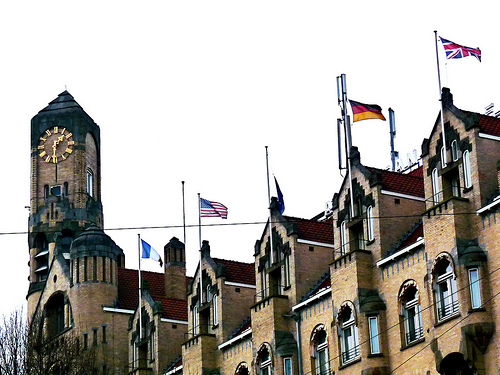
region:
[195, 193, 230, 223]
Flag of the United States of America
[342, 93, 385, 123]
Flag of Germany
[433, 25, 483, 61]
Flag of Great Britain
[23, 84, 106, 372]
Clock tower with green roof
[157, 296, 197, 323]
Red roof tiles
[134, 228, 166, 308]
Blue, white, and black flag hoisted on flag pole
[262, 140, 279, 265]
Flag pole with no flag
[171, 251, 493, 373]
Windows along a building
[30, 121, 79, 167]
Clock with hands at 1:30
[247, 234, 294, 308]
Balcony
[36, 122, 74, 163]
Bronze colored metal clock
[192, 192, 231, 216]
America flag on flagpole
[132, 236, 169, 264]
French flag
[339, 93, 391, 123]
Flag of germany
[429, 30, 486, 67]
Flag of the United Kingdom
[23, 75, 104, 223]
Clocktower made of bricks and metal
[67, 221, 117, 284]
Parapet attached to clock tower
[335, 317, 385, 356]
Window built into brick building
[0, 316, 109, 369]
Tree with no leaves on it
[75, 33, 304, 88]
Pale white sky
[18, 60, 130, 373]
an outside clock on a building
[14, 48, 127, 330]
an outside clock building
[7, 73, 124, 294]
a clock with golden numbers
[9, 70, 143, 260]
a clock with golden arms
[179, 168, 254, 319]
american flag on top of building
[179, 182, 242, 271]
a flag with red stripes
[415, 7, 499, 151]
A British flag on building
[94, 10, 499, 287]
flags flying in the air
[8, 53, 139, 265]
a large outside clock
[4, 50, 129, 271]
a clock at the top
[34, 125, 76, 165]
a clock on top of the tower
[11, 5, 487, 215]
the sky above the building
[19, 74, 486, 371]
a very large and fancy building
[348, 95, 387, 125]
a flag on top of the building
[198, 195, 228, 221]
the united states flag on top of the building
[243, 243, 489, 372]
the windows in front of the building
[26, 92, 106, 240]
a tower with a clock on it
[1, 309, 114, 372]
a tree sticking out in front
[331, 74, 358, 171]
a pole on top of the building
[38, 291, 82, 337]
a very big window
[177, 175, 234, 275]
red and white flag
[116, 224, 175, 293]
blue and white flag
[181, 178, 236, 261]
american flag on a pole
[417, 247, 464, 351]
window with awning around it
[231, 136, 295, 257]
blue flag on pole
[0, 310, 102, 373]
trees with no leaves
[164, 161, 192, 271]
a tall silver pole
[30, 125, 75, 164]
gols roman numerals on clock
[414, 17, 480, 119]
a texas flag on pole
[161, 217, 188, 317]
stone pillar on roof